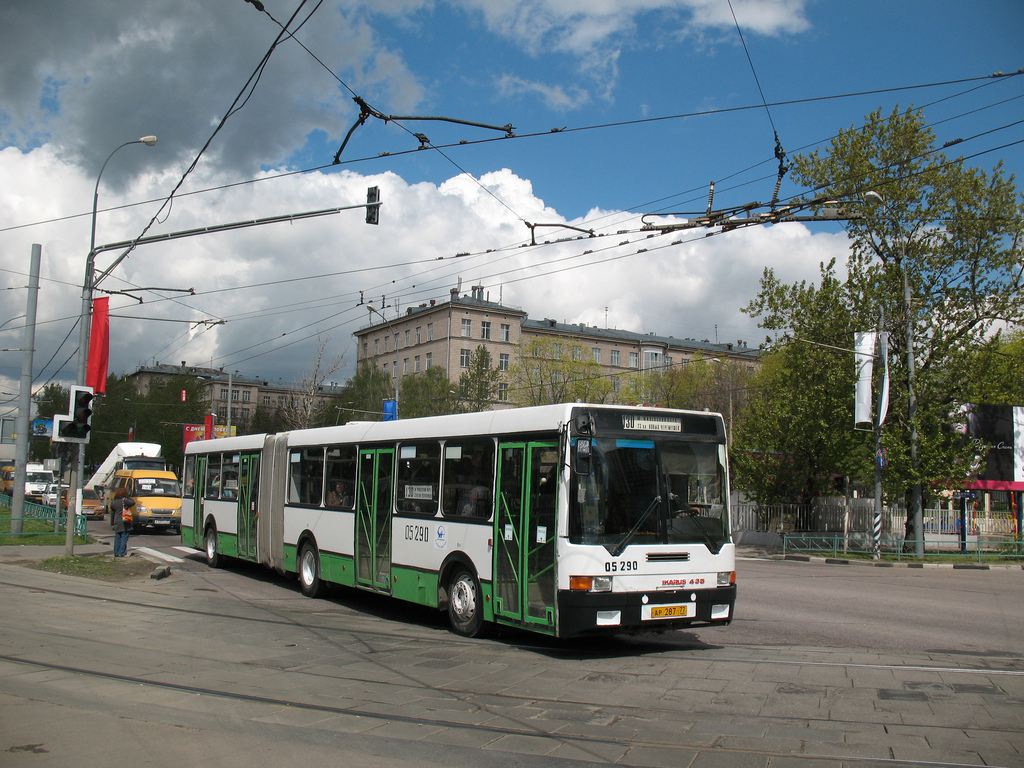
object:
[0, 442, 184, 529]
car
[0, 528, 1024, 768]
pavement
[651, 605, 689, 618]
license plate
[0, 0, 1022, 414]
clouds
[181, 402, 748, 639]
green/white bus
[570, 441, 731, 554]
bus/front window